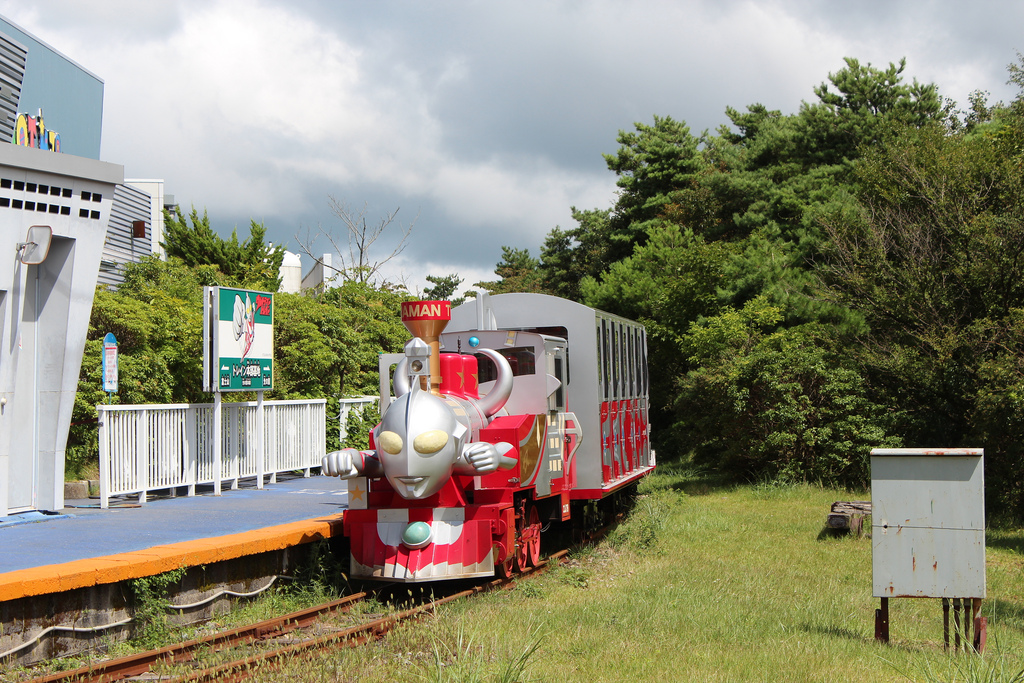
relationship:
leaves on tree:
[662, 298, 771, 413] [532, 82, 986, 443]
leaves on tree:
[683, 350, 755, 430] [593, 168, 913, 454]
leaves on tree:
[874, 313, 935, 407] [602, 112, 948, 421]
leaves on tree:
[856, 266, 990, 435] [565, 73, 965, 488]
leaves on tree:
[832, 97, 930, 206] [616, 108, 952, 476]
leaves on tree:
[699, 205, 846, 342] [558, 104, 973, 481]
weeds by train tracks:
[240, 605, 444, 670] [229, 590, 422, 655]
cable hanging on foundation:
[11, 564, 297, 657] [11, 530, 333, 654]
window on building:
[9, 176, 29, 190] [7, 147, 128, 491]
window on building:
[10, 176, 106, 229] [1, 35, 166, 517]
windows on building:
[1, 180, 110, 226] [1, 35, 166, 517]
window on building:
[5, 176, 112, 226] [1, 35, 166, 517]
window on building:
[1, 180, 110, 219] [10, 14, 168, 514]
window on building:
[1, 163, 110, 218] [16, 37, 166, 506]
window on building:
[1, 171, 105, 247] [10, 14, 168, 514]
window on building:
[5, 163, 105, 226] [1, 35, 166, 517]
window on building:
[5, 163, 105, 226] [10, 14, 168, 514]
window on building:
[1, 175, 107, 230] [10, 14, 168, 514]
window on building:
[5, 171, 105, 224] [2, 4, 180, 521]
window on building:
[6, 182, 106, 224] [2, 4, 180, 521]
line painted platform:
[41, 523, 245, 560] [45, 469, 272, 565]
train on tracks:
[304, 229, 713, 580] [235, 603, 404, 679]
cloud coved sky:
[267, 22, 589, 189] [445, 29, 590, 116]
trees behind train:
[91, 49, 1021, 480] [356, 272, 679, 599]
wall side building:
[87, 388, 362, 507] [2, 4, 180, 521]